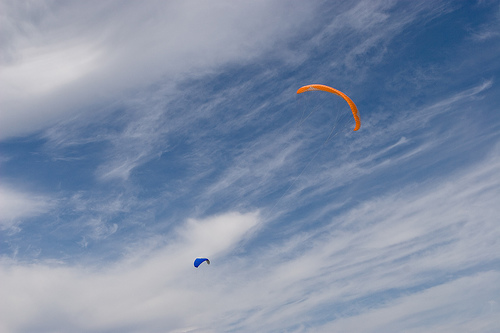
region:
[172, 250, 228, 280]
a blue sail in the sky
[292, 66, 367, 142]
a orange and white sails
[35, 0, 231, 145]
white clouds in the sky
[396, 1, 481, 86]
blue and white clouds in the sky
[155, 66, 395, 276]
a couple of sails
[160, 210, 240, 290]
a blue sail in a cloudy sky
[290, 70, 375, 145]
a orange and white sail in a cloudy sky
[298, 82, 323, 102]
white under the sail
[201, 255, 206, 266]
gray under the sail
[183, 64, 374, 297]
sails flying in the sky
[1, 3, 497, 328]
clouds in the sky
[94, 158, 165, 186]
thin white cloud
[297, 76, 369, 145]
orange kite in the sky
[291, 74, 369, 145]
kite is curved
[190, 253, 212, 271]
small bright blue kite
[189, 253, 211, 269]
blue kite in the sky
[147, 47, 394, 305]
two kites in the air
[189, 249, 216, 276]
kite soaring by a cloud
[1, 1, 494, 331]
blue sky visible behind the white clouds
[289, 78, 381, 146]
bright orange kire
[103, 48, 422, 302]
two kites flying in the sky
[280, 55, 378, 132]
an orange kite flying in the sky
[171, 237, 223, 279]
a blue kite flying in the sky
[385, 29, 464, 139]
partly cloudy blue skies over the scene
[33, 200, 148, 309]
fluffy white skies in the sky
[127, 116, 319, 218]
sparse stringy white clouds in the sky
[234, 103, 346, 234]
thin white strings of the orange kite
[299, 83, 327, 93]
white logo on the orange kite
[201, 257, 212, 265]
black underside of the blue kite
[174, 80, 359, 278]
two curved kites flying in the sky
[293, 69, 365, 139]
bright orange kite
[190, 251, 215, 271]
small blue kite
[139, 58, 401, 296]
two kites in the sky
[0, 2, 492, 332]
white clouds in the sky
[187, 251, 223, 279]
blue kite flying by the clouds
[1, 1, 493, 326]
bright blue sky visible betwen the clouds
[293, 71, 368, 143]
kite is rounded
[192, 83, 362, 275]
Man on an air float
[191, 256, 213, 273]
Man using the air float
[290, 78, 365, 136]
Orange air float held by the man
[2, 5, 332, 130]
Large cloud puff in the sky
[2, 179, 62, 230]
Small cloud puff in the sky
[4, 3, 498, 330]
Cloudy blue sky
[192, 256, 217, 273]
Man in the air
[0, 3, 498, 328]
Several clouds in the air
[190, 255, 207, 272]
Blue float held by the man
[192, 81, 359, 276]
Object in the air